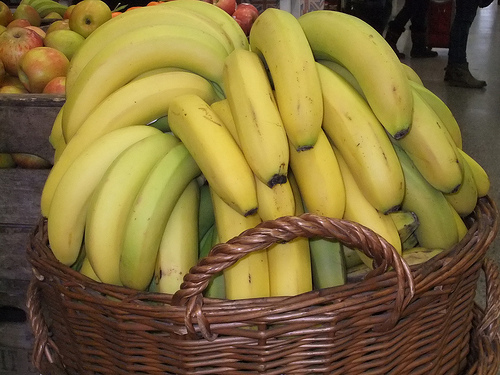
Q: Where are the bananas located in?
A: A basket.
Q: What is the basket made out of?
A: Woven.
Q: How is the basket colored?
A: Brown.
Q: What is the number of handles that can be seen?
A: One.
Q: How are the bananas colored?
A: Green and yellow.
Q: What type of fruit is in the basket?
A: Bananas.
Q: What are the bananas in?
A: Basket.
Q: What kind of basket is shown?
A: Wicker.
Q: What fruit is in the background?
A: Apples.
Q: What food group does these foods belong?
A: Fruit.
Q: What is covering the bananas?
A: Peels.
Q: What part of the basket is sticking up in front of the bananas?
A: Handle.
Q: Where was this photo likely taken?
A: Market.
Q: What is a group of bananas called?
A: Bunch.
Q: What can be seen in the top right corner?
A: Human foot.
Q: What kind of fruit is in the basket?
A: Bananas.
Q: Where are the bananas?
A: In the basket.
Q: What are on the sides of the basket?
A: Handles.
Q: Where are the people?
A: To the right of the basket.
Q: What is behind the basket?
A: Metal basket of apples.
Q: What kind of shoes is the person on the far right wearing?
A: Black boots.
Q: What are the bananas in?
A: Basket.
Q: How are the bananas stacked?
A: Upside down.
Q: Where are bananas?
A: In a basket.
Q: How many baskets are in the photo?
A: One.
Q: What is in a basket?
A: Bananas.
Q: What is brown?
A: A bakset.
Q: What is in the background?
A: Apples.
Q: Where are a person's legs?
A: In the distance.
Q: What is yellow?
A: The bananas.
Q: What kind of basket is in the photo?
A: Wicker.